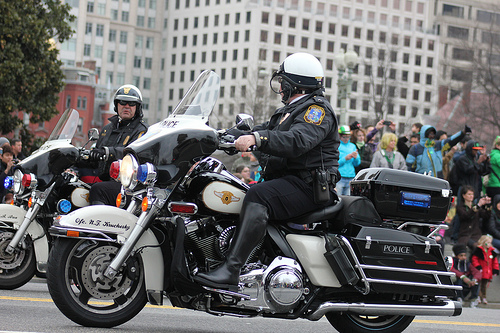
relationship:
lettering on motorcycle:
[380, 241, 420, 257] [35, 26, 480, 323]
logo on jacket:
[300, 103, 330, 130] [247, 88, 342, 188]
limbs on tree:
[482, 71, 498, 89] [459, 23, 498, 126]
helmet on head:
[269, 52, 325, 106] [270, 53, 323, 104]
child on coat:
[469, 231, 497, 312] [471, 242, 498, 279]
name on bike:
[72, 212, 128, 229] [46, 70, 463, 333]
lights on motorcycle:
[105, 156, 156, 195] [42, 111, 472, 313]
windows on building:
[229, 48, 240, 63] [162, 9, 487, 113]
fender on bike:
[58, 201, 163, 304] [43, 85, 473, 331]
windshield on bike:
[165, 66, 227, 129] [43, 85, 473, 331]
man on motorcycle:
[198, 46, 345, 289] [1, 107, 107, 288]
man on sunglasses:
[97, 82, 147, 132] [115, 95, 141, 107]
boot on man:
[187, 208, 303, 296] [192, 52, 342, 294]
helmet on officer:
[281, 52, 317, 87] [228, 48, 345, 286]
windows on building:
[76, 92, 91, 109] [126, 0, 477, 105]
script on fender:
[71, 215, 136, 230] [46, 189, 166, 254]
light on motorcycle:
[137, 164, 149, 183] [47, 111, 465, 331]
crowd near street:
[342, 118, 468, 169] [264, 300, 483, 325]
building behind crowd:
[38, 1, 498, 141] [349, 119, 453, 159]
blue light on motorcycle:
[36, 191, 81, 230] [112, 141, 448, 305]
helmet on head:
[269, 52, 325, 106] [275, 53, 329, 97]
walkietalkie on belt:
[311, 162, 334, 207] [288, 166, 350, 178]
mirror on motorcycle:
[232, 112, 265, 129] [128, 145, 442, 310]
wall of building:
[58, 90, 93, 122] [171, 7, 295, 68]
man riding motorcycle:
[198, 46, 345, 289] [89, 150, 447, 299]